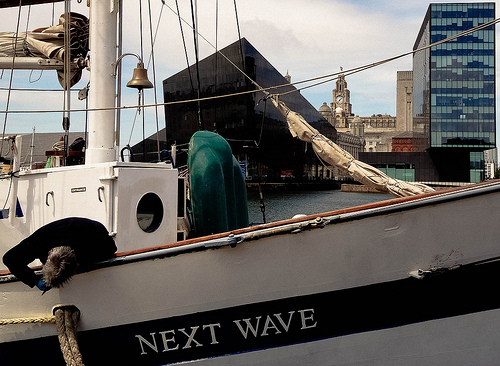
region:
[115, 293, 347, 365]
white writing on the boat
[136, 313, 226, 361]
the word "next" on the boat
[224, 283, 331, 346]
the word "wave" on the boat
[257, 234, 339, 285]
white part of the boat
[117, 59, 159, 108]
bell on the boat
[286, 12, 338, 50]
clouds above the land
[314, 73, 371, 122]
building in the background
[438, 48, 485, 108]
windows on the building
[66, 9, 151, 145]
white pole on boat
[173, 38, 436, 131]
rope above the boat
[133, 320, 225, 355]
The word NEXT in white letters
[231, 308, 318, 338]
The white lettering of the word WAVE on the boat.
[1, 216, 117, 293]
A man in black bent over the boat with a blue glove on.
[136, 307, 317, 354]
NEXT WAVE in white letters on the boat.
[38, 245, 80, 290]
Grey hair on a man bent over the boat.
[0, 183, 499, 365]
The black and white side of a boat that says NEXT WAVE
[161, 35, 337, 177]
A black building past the ship.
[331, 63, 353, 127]
A tall brown tower with a clock on it past the ship.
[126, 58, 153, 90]
A small gold bell on the boat.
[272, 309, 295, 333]
White letter V in WAVE.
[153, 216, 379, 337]
This is a picture of a boat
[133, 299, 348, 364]
The boat says "Next wave"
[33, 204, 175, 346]
This is a man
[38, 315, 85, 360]
This is a rope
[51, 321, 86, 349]
The rope is light bown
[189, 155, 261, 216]
This is a seat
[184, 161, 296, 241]
The seat is green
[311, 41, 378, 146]
This is a building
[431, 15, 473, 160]
The building is made of glass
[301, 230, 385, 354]
The boat is white and navy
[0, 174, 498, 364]
A large white boat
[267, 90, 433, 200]
A rolled up mast on the boat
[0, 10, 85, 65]
A rolled up mast on the boat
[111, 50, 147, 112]
A bell on the boat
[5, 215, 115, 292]
A person in a black jacket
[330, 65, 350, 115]
A large clock tower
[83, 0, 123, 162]
A large white pole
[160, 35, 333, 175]
A large black building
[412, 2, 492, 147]
A large office building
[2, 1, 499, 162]
A cloudy blue sky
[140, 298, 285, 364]
This sign says the "Next Wave"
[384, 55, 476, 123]
This is a building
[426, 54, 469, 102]
The building is made of glass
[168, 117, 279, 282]
This is a green seat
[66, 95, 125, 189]
This is a white pole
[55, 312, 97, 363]
This is a picture of a rope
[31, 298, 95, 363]
The rope is light brown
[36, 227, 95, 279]
This is a person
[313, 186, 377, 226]
This is the harbor